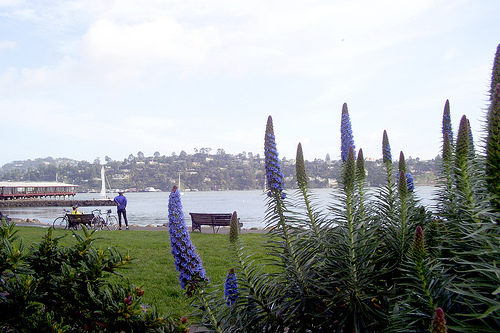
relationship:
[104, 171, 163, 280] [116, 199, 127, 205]
man wearing purple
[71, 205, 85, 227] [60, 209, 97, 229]
person sitting on bench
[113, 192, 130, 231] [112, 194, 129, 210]
man wearing a shirt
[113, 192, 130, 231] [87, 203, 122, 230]
man by a bicycle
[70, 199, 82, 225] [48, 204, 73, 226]
person by a bicycle